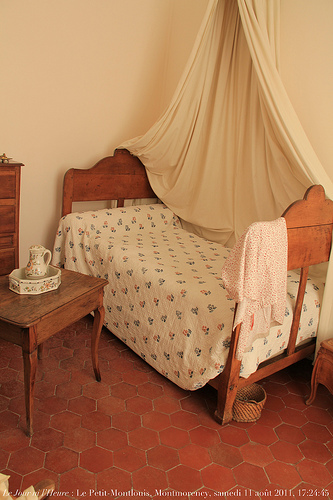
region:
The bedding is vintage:
[108, 224, 225, 344]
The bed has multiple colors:
[62, 192, 250, 350]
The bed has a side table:
[15, 242, 107, 389]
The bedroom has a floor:
[134, 413, 233, 460]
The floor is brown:
[117, 388, 231, 498]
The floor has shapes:
[107, 426, 231, 489]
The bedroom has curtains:
[158, 117, 324, 226]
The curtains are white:
[193, 27, 294, 200]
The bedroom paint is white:
[26, 75, 131, 153]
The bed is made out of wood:
[81, 164, 132, 184]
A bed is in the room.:
[52, 138, 332, 425]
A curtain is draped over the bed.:
[111, 1, 317, 249]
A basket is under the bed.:
[214, 379, 279, 432]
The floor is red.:
[0, 398, 331, 495]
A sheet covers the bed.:
[60, 207, 329, 393]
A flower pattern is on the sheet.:
[120, 279, 217, 367]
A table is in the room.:
[1, 235, 133, 452]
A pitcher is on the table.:
[13, 236, 72, 283]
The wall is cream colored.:
[0, 0, 203, 148]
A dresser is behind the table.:
[0, 146, 41, 305]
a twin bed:
[69, 146, 332, 385]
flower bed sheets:
[62, 192, 281, 389]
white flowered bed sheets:
[66, 200, 242, 347]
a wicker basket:
[203, 375, 283, 423]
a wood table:
[0, 251, 116, 390]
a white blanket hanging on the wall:
[165, 0, 324, 207]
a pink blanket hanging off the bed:
[226, 205, 310, 363]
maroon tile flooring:
[73, 396, 332, 469]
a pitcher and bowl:
[9, 232, 91, 305]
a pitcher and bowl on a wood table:
[0, 242, 89, 312]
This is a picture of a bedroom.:
[16, 100, 320, 486]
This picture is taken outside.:
[34, 171, 319, 480]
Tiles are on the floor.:
[24, 359, 317, 490]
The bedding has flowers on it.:
[76, 194, 257, 423]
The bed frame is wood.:
[237, 181, 294, 416]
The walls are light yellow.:
[40, 15, 294, 147]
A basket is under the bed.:
[230, 366, 298, 441]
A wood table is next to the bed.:
[0, 238, 131, 438]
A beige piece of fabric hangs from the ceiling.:
[100, 15, 327, 290]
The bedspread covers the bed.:
[74, 146, 311, 392]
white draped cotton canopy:
[142, 50, 313, 145]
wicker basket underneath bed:
[216, 374, 281, 421]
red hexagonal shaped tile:
[82, 428, 242, 473]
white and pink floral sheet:
[202, 208, 303, 380]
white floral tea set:
[15, 238, 68, 301]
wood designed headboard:
[52, 159, 138, 200]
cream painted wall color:
[22, 37, 116, 74]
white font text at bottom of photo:
[14, 489, 331, 499]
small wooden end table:
[310, 346, 325, 369]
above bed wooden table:
[9, 306, 124, 378]